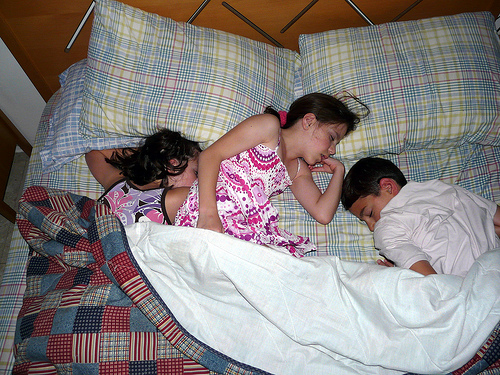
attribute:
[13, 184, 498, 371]
blanket — red, white, blue, patch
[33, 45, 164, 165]
pillow — blue, big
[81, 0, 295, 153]
pillow — blue, big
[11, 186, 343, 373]
blanket — quilted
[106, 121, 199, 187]
hair — brown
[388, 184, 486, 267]
shirt — white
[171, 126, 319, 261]
dress — pink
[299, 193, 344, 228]
elbow — part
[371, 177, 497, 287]
shirt — white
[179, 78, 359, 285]
girl — young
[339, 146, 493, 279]
boy — young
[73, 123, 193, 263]
girl — sleeping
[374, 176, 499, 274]
shirt — white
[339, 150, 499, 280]
kid — sleeping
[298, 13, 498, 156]
pillow — blue, big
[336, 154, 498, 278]
boy — sleeping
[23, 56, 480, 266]
sheets — blue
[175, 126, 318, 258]
pattern — paisley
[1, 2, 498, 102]
head board — brown, wooden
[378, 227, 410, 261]
sleeve — part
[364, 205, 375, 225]
eyes — closed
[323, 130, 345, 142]
eyes — closed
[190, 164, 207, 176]
eyes — closed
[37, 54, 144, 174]
small pillow — blue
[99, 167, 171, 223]
shirt — purple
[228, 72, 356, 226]
girl — sleeping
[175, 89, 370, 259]
kid — sleeping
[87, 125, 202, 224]
kid — sleeping